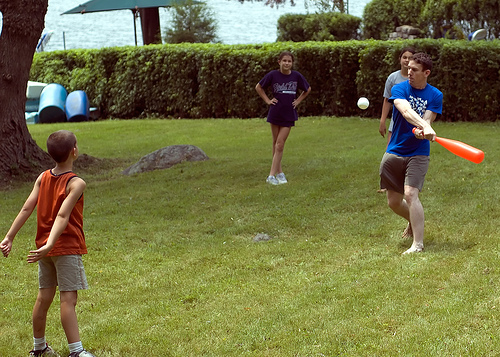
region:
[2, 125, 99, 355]
boy standing on grass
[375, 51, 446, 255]
boy standing on grass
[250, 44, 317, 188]
person standing on grass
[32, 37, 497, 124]
green hedge behind person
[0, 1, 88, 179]
tree next to person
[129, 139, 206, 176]
rock next to person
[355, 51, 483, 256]
man swinging at white ball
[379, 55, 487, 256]
man wearing blue shirt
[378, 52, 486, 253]
man holding orange plastic bat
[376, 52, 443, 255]
A man swinging at a ball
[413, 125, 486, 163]
An orange bat in the man's hands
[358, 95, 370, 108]
A white ball in the air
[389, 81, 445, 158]
A blue shirt on the man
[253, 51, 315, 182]
A girl with her hands on her hips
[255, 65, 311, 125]
A dark shirt on the girl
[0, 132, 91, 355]
A boy with his hands back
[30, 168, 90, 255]
An orange shirt on the boy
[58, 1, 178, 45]
A large green umbrella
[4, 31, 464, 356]
Four people in the image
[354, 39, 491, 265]
Young man is holding a plastic bat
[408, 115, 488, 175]
The bat is orange in color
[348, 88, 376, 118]
A ball in the air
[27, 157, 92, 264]
Young boy is wearing an orange tank top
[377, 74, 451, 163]
Young man is wearing a blue shirt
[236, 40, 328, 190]
A young woman in the background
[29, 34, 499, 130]
A bush in the background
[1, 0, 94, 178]
A tree truck in the background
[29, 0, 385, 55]
water behind the hedge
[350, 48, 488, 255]
a boy swinging a baseball bat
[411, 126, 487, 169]
the bat is orange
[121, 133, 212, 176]
a rock in the grass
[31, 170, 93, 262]
his shirt is orange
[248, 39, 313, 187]
a girl on the grass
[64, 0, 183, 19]
a parasol behind the hedge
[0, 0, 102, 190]
a tree coming out of the grass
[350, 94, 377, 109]
the ball is white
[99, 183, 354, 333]
it is a playground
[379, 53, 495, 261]
man holding bat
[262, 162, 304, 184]
girl wearing white color shoe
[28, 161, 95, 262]
boy wearing orange shirt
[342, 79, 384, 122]
it is a white color ball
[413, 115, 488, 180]
it is a red color bat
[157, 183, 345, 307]
it is green color grass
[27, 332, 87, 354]
boy wearing white shocks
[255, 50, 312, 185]
Girl in a black shirt standing under the tree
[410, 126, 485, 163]
Orange plastic bat in the man's hands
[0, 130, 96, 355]
Boy in orange shirt and tan shorts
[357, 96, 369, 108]
Sports ball in mid air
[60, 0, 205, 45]
Umbrella visible behind the hedge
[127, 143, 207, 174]
Rock visible under the tree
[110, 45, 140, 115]
hedge bush by the grass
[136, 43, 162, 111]
hedge bush by the grass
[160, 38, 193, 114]
hedge bush by the grass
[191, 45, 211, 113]
hedge bush by the grass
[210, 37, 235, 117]
hedge bush by the grass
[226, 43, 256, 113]
hedge bush by the grass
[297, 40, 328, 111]
hedge bush by the grass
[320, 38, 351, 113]
hedge bush by the grass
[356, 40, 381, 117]
hedge bush by the grass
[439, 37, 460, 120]
hedge bush by the grass